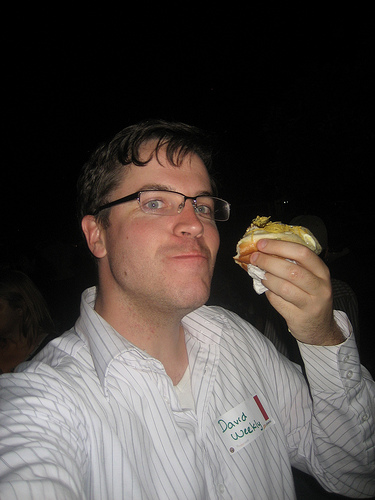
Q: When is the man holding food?
A: Now.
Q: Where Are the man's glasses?
A: Face.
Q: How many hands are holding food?
A: One.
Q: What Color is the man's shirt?
A: White.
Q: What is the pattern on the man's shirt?
A: Stripes.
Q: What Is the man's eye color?
A: Blue.